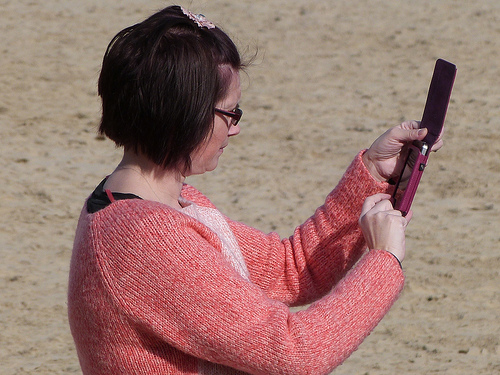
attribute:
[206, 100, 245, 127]
eye glasses — for eye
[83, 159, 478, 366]
sweater —  peach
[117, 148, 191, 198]
womans neck —  woman's 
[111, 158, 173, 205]
necklace —  thin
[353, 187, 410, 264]
hand —  woman's , the right 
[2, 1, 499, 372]
sand —  brown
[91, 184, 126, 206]
shirt — black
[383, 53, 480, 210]
cell phone —   plum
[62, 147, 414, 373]
sweater —  pink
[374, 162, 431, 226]
case — purple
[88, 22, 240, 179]
hair — dark brown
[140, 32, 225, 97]
hair —  sticking up,  woman's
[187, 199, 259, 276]
shirt —  pink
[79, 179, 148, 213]
black shirt —  black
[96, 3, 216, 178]
hair —  black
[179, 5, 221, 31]
bow —  pink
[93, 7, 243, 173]
head —  hers